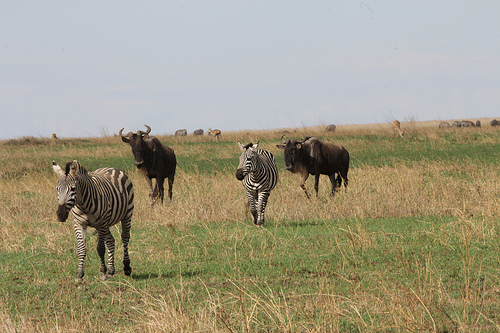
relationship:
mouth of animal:
[52, 210, 70, 223] [52, 159, 135, 285]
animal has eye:
[52, 159, 135, 285] [70, 185, 76, 192]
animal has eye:
[52, 159, 135, 285] [56, 187, 60, 193]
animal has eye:
[235, 139, 280, 228] [245, 156, 260, 165]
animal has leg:
[235, 139, 280, 228] [257, 190, 267, 224]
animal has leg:
[235, 139, 280, 228] [246, 188, 257, 222]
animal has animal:
[235, 139, 280, 228] [235, 139, 280, 228]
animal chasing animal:
[119, 124, 177, 207] [52, 159, 135, 285]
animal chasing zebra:
[276, 133, 351, 199] [229, 137, 283, 231]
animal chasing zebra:
[276, 133, 351, 199] [230, 112, 296, 246]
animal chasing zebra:
[119, 124, 177, 207] [50, 159, 135, 277]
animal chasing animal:
[276, 133, 351, 199] [235, 139, 280, 228]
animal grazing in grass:
[173, 127, 189, 139] [0, 121, 499, 331]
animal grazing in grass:
[189, 127, 205, 137] [0, 121, 499, 331]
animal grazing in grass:
[206, 127, 224, 137] [0, 121, 499, 331]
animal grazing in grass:
[326, 123, 338, 131] [0, 121, 499, 331]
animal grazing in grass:
[388, 118, 404, 134] [0, 121, 499, 331]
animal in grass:
[276, 133, 351, 199] [0, 121, 499, 331]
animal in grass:
[228, 139, 281, 230] [0, 121, 499, 331]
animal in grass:
[119, 124, 177, 207] [0, 121, 499, 331]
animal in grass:
[45, 157, 142, 284] [0, 121, 499, 331]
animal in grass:
[52, 159, 135, 285] [0, 121, 499, 331]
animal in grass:
[235, 139, 280, 228] [0, 121, 499, 331]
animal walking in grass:
[270, 137, 357, 204] [135, 176, 496, 331]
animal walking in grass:
[235, 139, 280, 228] [135, 176, 496, 331]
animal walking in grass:
[120, 123, 175, 200] [135, 176, 496, 331]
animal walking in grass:
[52, 159, 135, 285] [135, 176, 496, 331]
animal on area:
[52, 159, 135, 285] [0, 121, 500, 333]